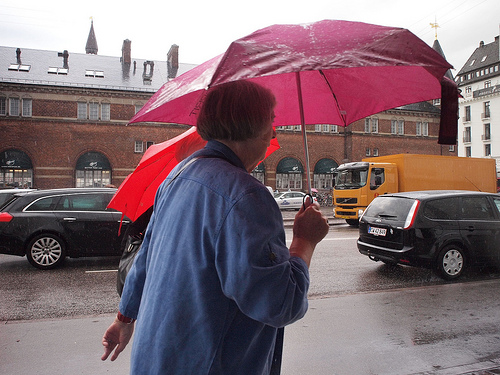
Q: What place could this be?
A: It is a road.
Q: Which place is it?
A: It is a road.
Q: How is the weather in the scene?
A: It is rainy.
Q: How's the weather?
A: It is rainy.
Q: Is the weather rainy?
A: Yes, it is rainy.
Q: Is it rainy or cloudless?
A: It is rainy.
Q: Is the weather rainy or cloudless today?
A: It is rainy.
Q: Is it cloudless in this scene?
A: No, it is rainy.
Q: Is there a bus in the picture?
A: No, there are no buses.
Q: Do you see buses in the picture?
A: No, there are no buses.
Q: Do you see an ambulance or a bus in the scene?
A: No, there are no buses or ambulances.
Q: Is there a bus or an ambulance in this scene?
A: No, there are no buses or ambulances.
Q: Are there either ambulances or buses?
A: No, there are no buses or ambulances.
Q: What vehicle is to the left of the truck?
A: The vehicle is a car.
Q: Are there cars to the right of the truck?
A: No, the car is to the left of the truck.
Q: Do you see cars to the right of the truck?
A: No, the car is to the left of the truck.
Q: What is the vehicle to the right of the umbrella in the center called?
A: The vehicle is a car.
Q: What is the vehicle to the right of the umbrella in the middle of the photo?
A: The vehicle is a car.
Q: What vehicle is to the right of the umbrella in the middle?
A: The vehicle is a car.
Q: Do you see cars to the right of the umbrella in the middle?
A: Yes, there is a car to the right of the umbrella.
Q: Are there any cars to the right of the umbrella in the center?
A: Yes, there is a car to the right of the umbrella.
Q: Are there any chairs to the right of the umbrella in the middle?
A: No, there is a car to the right of the umbrella.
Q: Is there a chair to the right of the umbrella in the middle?
A: No, there is a car to the right of the umbrella.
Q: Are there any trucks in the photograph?
A: Yes, there is a truck.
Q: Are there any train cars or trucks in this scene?
A: Yes, there is a truck.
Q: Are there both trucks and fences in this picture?
A: No, there is a truck but no fences.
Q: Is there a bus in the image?
A: No, there are no buses.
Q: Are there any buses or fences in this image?
A: No, there are no buses or fences.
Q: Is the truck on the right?
A: Yes, the truck is on the right of the image.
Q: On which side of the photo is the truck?
A: The truck is on the right of the image.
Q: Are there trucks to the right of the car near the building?
A: Yes, there is a truck to the right of the car.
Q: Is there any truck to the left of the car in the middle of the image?
A: No, the truck is to the right of the car.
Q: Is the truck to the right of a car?
A: Yes, the truck is to the right of a car.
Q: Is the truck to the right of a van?
A: No, the truck is to the right of a car.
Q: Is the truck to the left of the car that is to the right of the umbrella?
A: No, the truck is to the right of the car.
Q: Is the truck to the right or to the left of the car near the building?
A: The truck is to the right of the car.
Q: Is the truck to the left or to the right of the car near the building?
A: The truck is to the right of the car.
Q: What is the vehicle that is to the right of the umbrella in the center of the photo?
A: The vehicle is a truck.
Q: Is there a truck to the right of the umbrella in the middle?
A: Yes, there is a truck to the right of the umbrella.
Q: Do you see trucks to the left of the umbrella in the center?
A: No, the truck is to the right of the umbrella.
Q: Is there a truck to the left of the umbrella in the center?
A: No, the truck is to the right of the umbrella.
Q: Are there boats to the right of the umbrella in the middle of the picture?
A: No, there is a truck to the right of the umbrella.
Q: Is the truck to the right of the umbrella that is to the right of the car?
A: Yes, the truck is to the right of the umbrella.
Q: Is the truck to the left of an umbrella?
A: No, the truck is to the right of an umbrella.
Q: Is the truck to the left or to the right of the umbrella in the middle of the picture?
A: The truck is to the right of the umbrella.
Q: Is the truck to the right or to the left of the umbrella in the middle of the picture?
A: The truck is to the right of the umbrella.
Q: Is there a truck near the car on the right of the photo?
A: Yes, there is a truck near the car.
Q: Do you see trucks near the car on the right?
A: Yes, there is a truck near the car.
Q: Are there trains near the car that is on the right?
A: No, there is a truck near the car.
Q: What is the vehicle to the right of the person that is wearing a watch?
A: The vehicle is a truck.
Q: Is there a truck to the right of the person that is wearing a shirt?
A: Yes, there is a truck to the right of the person.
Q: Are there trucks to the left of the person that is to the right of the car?
A: No, the truck is to the right of the person.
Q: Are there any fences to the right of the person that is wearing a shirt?
A: No, there is a truck to the right of the person.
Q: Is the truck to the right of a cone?
A: No, the truck is to the right of a person.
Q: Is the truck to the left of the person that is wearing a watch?
A: No, the truck is to the right of the person.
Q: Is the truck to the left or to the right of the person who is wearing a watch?
A: The truck is to the right of the person.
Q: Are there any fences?
A: No, there are no fences.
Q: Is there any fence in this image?
A: No, there are no fences.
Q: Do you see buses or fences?
A: No, there are no fences or buses.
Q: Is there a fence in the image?
A: No, there are no fences.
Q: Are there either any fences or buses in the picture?
A: No, there are no fences or buses.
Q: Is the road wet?
A: Yes, the road is wet.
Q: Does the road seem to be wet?
A: Yes, the road is wet.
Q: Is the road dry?
A: No, the road is wet.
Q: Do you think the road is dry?
A: No, the road is wet.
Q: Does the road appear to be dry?
A: No, the road is wet.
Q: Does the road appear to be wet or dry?
A: The road is wet.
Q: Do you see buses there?
A: No, there are no buses.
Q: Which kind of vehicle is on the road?
A: The vehicle is a car.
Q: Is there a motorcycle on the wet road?
A: No, there is a car on the road.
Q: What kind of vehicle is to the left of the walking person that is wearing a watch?
A: The vehicle is a car.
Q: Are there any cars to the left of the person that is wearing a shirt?
A: Yes, there is a car to the left of the person.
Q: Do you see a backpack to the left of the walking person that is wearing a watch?
A: No, there is a car to the left of the person.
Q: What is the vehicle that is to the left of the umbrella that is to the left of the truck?
A: The vehicle is a car.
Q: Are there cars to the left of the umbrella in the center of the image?
A: Yes, there is a car to the left of the umbrella.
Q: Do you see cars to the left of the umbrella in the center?
A: Yes, there is a car to the left of the umbrella.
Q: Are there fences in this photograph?
A: No, there are no fences.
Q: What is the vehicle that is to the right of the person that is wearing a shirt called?
A: The vehicle is a car.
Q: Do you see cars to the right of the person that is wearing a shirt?
A: Yes, there is a car to the right of the person.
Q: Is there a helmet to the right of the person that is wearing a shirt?
A: No, there is a car to the right of the person.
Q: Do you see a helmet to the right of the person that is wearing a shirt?
A: No, there is a car to the right of the person.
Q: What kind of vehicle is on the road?
A: The vehicle is a car.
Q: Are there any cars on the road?
A: Yes, there is a car on the road.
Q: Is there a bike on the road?
A: No, there is a car on the road.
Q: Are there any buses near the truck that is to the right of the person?
A: No, there is a car near the truck.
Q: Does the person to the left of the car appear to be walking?
A: Yes, the person is walking.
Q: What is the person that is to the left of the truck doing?
A: The person is walking.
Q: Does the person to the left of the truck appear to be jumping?
A: No, the person is walking.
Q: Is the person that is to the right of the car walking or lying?
A: The person is walking.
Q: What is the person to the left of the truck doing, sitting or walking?
A: The person is walking.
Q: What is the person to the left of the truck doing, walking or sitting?
A: The person is walking.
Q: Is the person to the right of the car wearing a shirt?
A: Yes, the person is wearing a shirt.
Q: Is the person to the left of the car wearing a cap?
A: No, the person is wearing a shirt.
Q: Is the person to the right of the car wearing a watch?
A: Yes, the person is wearing a watch.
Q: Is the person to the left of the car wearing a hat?
A: No, the person is wearing a watch.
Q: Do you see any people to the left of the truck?
A: Yes, there is a person to the left of the truck.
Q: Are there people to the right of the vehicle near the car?
A: No, the person is to the left of the truck.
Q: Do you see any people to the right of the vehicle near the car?
A: No, the person is to the left of the truck.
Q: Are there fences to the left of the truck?
A: No, there is a person to the left of the truck.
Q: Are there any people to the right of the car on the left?
A: Yes, there is a person to the right of the car.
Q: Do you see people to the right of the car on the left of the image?
A: Yes, there is a person to the right of the car.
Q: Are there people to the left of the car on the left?
A: No, the person is to the right of the car.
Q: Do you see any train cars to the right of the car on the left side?
A: No, there is a person to the right of the car.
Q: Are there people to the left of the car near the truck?
A: Yes, there is a person to the left of the car.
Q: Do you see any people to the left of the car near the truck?
A: Yes, there is a person to the left of the car.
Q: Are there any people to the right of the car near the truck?
A: No, the person is to the left of the car.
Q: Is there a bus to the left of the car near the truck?
A: No, there is a person to the left of the car.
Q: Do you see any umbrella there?
A: Yes, there is an umbrella.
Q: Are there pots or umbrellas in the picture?
A: Yes, there is an umbrella.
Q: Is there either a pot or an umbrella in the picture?
A: Yes, there is an umbrella.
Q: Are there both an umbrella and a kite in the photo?
A: No, there is an umbrella but no kites.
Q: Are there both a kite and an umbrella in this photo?
A: No, there is an umbrella but no kites.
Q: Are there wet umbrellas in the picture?
A: Yes, there is a wet umbrella.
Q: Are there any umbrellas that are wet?
A: Yes, there is an umbrella that is wet.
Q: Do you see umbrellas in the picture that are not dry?
A: Yes, there is a wet umbrella.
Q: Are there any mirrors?
A: No, there are no mirrors.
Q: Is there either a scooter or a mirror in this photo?
A: No, there are no mirrors or scooters.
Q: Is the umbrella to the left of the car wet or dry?
A: The umbrella is wet.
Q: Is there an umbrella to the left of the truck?
A: Yes, there is an umbrella to the left of the truck.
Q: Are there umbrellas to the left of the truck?
A: Yes, there is an umbrella to the left of the truck.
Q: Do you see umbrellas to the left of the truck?
A: Yes, there is an umbrella to the left of the truck.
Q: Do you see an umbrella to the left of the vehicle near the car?
A: Yes, there is an umbrella to the left of the truck.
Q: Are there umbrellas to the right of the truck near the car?
A: No, the umbrella is to the left of the truck.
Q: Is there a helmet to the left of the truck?
A: No, there is an umbrella to the left of the truck.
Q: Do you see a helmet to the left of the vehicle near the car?
A: No, there is an umbrella to the left of the truck.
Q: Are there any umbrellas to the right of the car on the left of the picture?
A: Yes, there is an umbrella to the right of the car.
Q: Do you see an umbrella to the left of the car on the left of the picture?
A: No, the umbrella is to the right of the car.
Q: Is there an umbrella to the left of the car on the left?
A: No, the umbrella is to the right of the car.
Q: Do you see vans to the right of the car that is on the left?
A: No, there is an umbrella to the right of the car.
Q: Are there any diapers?
A: No, there are no diapers.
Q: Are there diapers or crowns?
A: No, there are no diapers or crowns.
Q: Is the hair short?
A: Yes, the hair is short.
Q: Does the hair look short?
A: Yes, the hair is short.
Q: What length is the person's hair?
A: The hair is short.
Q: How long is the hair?
A: The hair is short.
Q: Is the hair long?
A: No, the hair is short.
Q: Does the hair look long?
A: No, the hair is short.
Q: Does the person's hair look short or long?
A: The hair is short.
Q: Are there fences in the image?
A: No, there are no fences.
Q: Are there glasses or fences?
A: No, there are no fences or glasses.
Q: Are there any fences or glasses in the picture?
A: No, there are no fences or glasses.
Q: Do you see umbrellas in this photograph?
A: Yes, there is an umbrella.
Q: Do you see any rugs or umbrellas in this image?
A: Yes, there is an umbrella.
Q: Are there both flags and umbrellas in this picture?
A: No, there is an umbrella but no flags.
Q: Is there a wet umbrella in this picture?
A: Yes, there is a wet umbrella.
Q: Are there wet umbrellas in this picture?
A: Yes, there is a wet umbrella.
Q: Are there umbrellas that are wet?
A: Yes, there is an umbrella that is wet.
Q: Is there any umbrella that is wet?
A: Yes, there is an umbrella that is wet.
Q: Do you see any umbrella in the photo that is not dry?
A: Yes, there is a wet umbrella.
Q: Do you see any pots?
A: No, there are no pots.